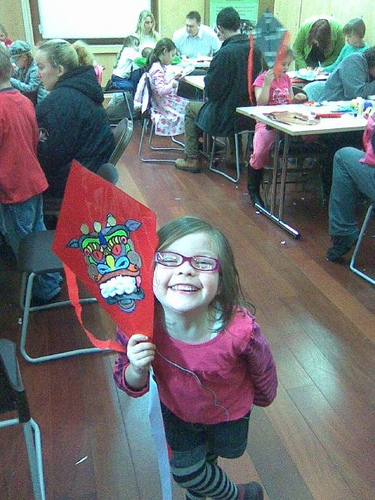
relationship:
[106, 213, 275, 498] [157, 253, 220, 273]
girl wearing glasses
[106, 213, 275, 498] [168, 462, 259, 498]
girl wearing socks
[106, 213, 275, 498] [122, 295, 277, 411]
girl wearing shirt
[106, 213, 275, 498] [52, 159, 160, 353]
girl holding kite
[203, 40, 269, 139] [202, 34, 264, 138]
man wearing jacket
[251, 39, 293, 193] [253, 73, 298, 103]
girl wearing pink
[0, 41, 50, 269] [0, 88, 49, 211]
boy wearing shirt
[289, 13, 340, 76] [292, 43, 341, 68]
adult wearing green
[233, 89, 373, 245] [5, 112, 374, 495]
table on ground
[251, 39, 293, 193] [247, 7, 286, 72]
girl holding kite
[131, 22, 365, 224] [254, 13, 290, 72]
kids crafting kites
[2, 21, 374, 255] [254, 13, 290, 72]
adults crafting kites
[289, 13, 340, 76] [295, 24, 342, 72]
person wearing jacket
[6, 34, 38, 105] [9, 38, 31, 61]
girl wearing cap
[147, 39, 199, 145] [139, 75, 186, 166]
girl in chair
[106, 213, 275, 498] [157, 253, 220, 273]
girl has glasses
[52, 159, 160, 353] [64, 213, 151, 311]
kite has design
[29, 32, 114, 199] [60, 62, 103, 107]
woman has hood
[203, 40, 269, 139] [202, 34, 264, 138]
man has coat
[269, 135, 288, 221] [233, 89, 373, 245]
legs on table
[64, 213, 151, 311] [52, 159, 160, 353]
bull on kite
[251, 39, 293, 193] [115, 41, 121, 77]
girl has braid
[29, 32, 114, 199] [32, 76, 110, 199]
woman has jacket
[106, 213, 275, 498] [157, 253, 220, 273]
girl in glasses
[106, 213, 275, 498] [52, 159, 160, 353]
girl made kite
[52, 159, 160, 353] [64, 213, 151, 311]
kite has face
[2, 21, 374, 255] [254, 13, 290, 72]
people making kites